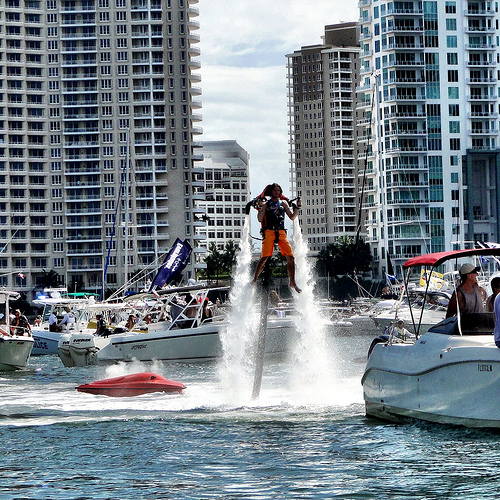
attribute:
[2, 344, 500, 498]
water — blue, white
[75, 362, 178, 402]
jet ski — red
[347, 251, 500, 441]
boat — white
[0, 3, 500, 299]
buildings — tall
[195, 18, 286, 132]
clouds — white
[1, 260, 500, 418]
boats — white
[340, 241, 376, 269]
leaves — green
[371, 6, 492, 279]
building — white, green, high rise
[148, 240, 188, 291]
banner — blue, dark blue, white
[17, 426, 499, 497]
ripples — blue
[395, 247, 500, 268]
hood — maroon, red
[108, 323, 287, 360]
stripes — black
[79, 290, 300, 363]
boat — white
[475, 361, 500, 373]
lettering — black, small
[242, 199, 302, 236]
jet pack — water powered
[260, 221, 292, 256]
shorts — orange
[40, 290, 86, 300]
roof — turquoise